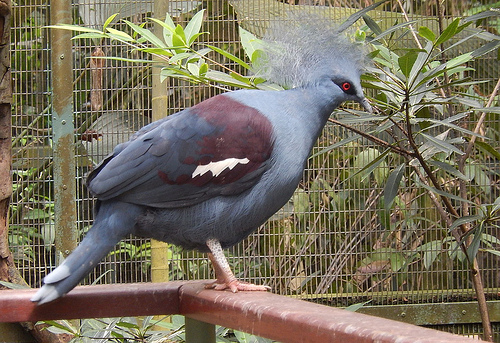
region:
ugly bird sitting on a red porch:
[32, 4, 430, 291]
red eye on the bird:
[336, 80, 354, 94]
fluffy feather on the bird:
[257, 5, 355, 82]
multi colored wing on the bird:
[88, 88, 279, 196]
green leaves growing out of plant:
[44, 13, 246, 88]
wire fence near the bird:
[310, 183, 397, 288]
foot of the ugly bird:
[203, 243, 272, 296]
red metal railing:
[8, 290, 283, 335]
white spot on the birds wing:
[190, 150, 249, 179]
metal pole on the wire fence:
[51, 10, 83, 254]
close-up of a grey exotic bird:
[23, 4, 382, 311]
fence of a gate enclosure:
[17, 8, 484, 287]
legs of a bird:
[197, 240, 271, 297]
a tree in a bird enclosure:
[360, 28, 498, 276]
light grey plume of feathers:
[253, 3, 370, 96]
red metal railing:
[181, 276, 391, 339]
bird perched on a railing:
[32, 13, 364, 324]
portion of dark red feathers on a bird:
[230, 120, 253, 143]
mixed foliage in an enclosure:
[326, 185, 432, 271]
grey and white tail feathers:
[20, 210, 128, 297]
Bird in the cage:
[73, 35, 320, 295]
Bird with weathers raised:
[258, 25, 357, 86]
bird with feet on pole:
[193, 225, 262, 299]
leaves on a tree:
[401, 109, 484, 254]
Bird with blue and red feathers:
[130, 118, 280, 195]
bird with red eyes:
[340, 72, 353, 100]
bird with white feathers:
[190, 149, 250, 183]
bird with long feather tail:
[23, 230, 126, 307]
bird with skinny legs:
[208, 235, 236, 277]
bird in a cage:
[133, 48, 383, 210]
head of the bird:
[307, 50, 390, 113]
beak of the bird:
[351, 86, 377, 118]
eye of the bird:
[325, 70, 365, 105]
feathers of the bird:
[107, 85, 291, 201]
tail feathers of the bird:
[28, 194, 135, 306]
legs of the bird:
[178, 225, 274, 319]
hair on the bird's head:
[263, 20, 351, 79]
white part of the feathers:
[179, 148, 264, 191]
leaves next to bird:
[128, 20, 228, 79]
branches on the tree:
[371, 105, 472, 227]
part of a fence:
[396, 240, 408, 248]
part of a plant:
[435, 140, 449, 154]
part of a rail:
[265, 308, 275, 318]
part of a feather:
[183, 172, 209, 212]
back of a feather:
[89, 216, 109, 245]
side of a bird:
[97, 219, 147, 341]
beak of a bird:
[363, 98, 374, 112]